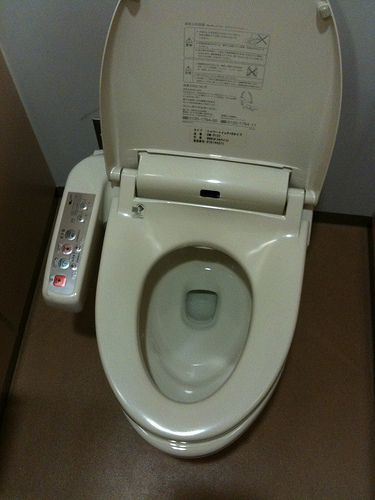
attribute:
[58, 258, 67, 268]
button — round, green 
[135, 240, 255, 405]
water — clear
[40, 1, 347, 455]
toilet — white, beige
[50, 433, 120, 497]
ground — brown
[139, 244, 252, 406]
bowl — empty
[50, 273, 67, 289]
button — red and black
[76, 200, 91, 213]
button — small, grey and black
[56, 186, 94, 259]
buttons — push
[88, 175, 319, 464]
toilet — white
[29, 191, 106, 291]
button — grey and black, small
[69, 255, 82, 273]
button — grey and black, small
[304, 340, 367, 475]
floor — brown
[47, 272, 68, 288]
button — red square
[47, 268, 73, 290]
button — red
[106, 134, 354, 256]
hinge — long